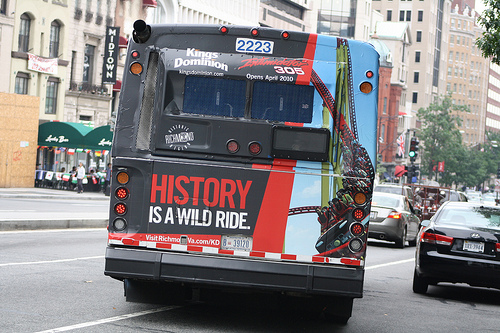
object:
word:
[214, 210, 250, 229]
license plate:
[220, 234, 252, 252]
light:
[408, 149, 416, 157]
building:
[0, 0, 118, 187]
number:
[262, 42, 270, 52]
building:
[439, 3, 490, 166]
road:
[0, 227, 499, 331]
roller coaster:
[314, 36, 374, 260]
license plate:
[461, 239, 483, 252]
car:
[411, 199, 500, 293]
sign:
[101, 25, 120, 83]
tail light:
[392, 214, 400, 219]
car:
[366, 190, 421, 249]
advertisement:
[109, 32, 380, 259]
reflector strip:
[280, 253, 296, 260]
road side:
[56, 263, 498, 332]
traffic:
[0, 0, 499, 332]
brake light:
[352, 206, 362, 219]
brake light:
[349, 221, 364, 235]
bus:
[103, 18, 380, 323]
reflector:
[116, 171, 131, 183]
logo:
[164, 124, 194, 150]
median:
[0, 196, 107, 232]